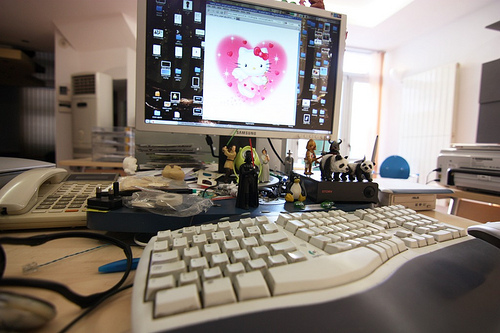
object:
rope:
[57, 273, 131, 333]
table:
[0, 208, 485, 328]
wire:
[0, 231, 133, 310]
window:
[203, 0, 302, 127]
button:
[267, 246, 382, 295]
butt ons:
[130, 203, 475, 332]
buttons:
[32, 192, 85, 213]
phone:
[0, 164, 124, 231]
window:
[337, 46, 384, 160]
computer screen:
[135, 0, 346, 141]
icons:
[153, 28, 163, 38]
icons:
[319, 67, 328, 77]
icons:
[161, 101, 172, 113]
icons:
[315, 32, 331, 55]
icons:
[194, 12, 202, 24]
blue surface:
[196, 94, 376, 211]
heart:
[216, 34, 288, 103]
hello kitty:
[232, 46, 270, 99]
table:
[372, 182, 454, 194]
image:
[201, 1, 304, 128]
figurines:
[222, 139, 377, 210]